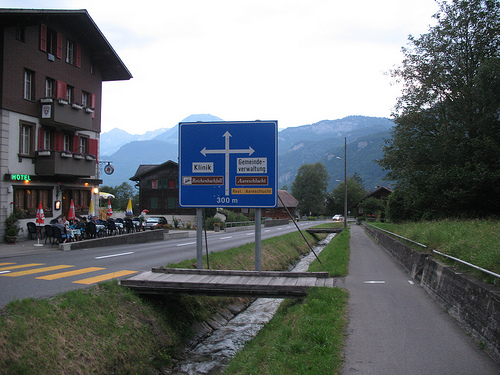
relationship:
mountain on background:
[280, 109, 397, 195] [91, 108, 413, 184]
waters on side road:
[171, 233, 336, 374] [179, 223, 347, 358]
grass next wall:
[368, 216, 499, 273] [357, 220, 498, 373]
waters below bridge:
[226, 314, 244, 346] [124, 250, 355, 308]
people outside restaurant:
[57, 211, 77, 242] [0, 10, 165, 250]